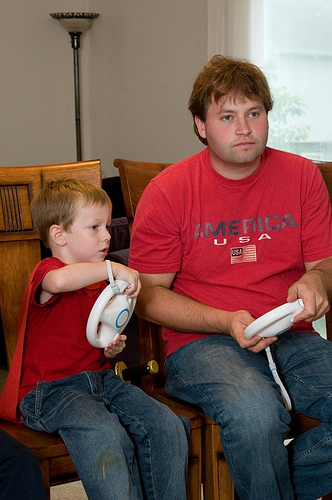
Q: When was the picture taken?
A: Daytime.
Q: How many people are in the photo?
A: Two.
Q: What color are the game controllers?
A: White.